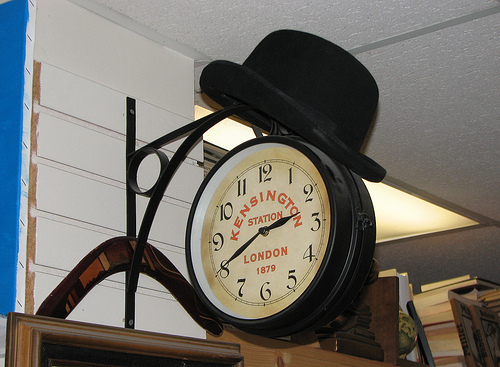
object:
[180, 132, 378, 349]
clock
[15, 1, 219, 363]
wall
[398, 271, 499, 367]
books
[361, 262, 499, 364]
shelf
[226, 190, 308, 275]
letters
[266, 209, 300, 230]
hand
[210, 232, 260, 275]
hand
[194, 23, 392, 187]
hat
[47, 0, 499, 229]
ceiling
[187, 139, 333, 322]
face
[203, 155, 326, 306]
numbers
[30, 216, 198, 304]
panel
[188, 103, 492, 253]
light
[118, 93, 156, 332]
pole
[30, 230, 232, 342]
boomerang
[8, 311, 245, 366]
frame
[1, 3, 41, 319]
tape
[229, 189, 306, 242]
kensington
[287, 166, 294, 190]
1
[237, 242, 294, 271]
london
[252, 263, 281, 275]
1879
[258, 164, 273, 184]
12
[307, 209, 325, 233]
3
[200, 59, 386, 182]
brim